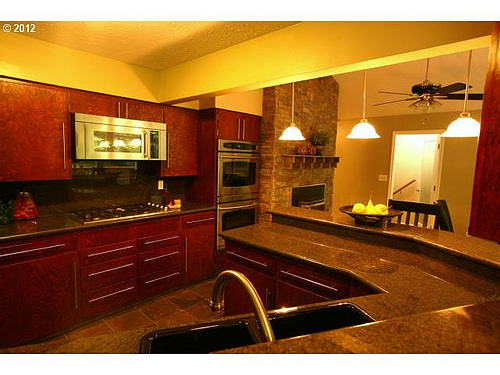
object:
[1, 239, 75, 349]
kitchen cabinets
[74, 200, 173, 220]
stovetop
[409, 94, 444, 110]
light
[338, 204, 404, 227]
bowl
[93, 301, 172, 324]
floor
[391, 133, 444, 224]
door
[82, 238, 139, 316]
cabinets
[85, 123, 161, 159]
microwave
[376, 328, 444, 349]
counter top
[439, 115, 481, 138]
light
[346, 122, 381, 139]
light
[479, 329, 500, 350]
countertops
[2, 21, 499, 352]
kitchen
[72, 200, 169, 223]
gas stove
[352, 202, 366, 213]
fruit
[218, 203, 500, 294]
counter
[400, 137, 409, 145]
lights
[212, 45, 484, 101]
ceiling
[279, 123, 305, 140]
light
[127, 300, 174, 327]
ground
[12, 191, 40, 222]
toaster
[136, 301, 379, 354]
sink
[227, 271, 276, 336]
neck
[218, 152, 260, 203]
oven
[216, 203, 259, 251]
oven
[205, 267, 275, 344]
faucet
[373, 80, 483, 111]
fan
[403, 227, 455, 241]
counter top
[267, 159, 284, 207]
wall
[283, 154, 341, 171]
shelf